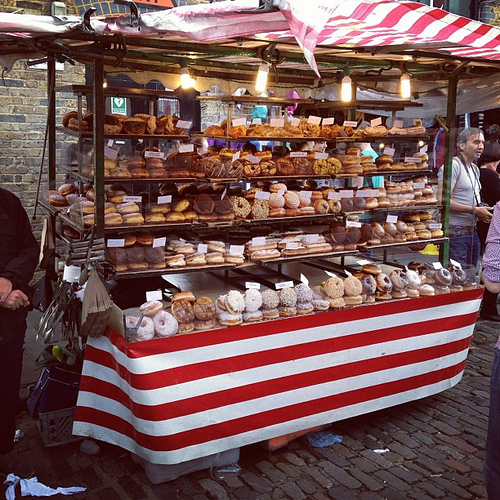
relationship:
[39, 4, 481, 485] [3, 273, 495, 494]
kiosk on sidewalk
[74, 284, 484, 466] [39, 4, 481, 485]
skirt around kiosk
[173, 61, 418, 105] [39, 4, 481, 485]
lights on kiosk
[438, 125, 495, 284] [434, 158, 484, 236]
man in shirt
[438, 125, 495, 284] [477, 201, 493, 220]
man wearing camera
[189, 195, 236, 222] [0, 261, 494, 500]
doughnuts on street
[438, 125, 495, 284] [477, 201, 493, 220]
man with camera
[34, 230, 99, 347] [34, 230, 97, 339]
tools for grabbing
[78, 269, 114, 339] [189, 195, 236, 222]
bags for doughnuts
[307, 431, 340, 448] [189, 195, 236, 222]
trash under doughnuts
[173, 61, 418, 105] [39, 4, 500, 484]
lights on kiosk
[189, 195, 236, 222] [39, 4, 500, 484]
doughnuts on kiosk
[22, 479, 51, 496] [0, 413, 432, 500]
litter on ground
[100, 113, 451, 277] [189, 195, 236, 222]
shelves of doughnuts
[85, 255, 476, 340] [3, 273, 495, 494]
table under sidewalk